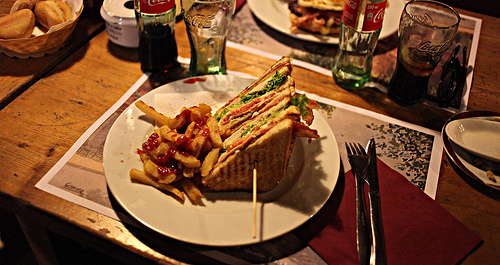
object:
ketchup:
[137, 110, 215, 177]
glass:
[179, 0, 237, 76]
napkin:
[298, 152, 486, 262]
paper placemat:
[382, 112, 447, 184]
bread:
[202, 119, 294, 192]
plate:
[102, 74, 342, 247]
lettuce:
[238, 71, 294, 106]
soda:
[332, 25, 375, 87]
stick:
[243, 167, 261, 239]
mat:
[36, 50, 443, 265]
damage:
[22, 100, 93, 143]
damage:
[474, 65, 491, 97]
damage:
[83, 214, 113, 235]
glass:
[398, 9, 450, 74]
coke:
[388, 61, 432, 102]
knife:
[367, 137, 388, 265]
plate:
[443, 118, 499, 163]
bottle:
[135, 1, 178, 74]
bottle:
[332, 2, 386, 90]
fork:
[342, 140, 372, 262]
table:
[2, 1, 499, 263]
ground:
[301, 67, 366, 109]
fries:
[129, 100, 220, 202]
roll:
[34, 0, 84, 32]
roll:
[0, 8, 34, 41]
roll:
[5, 0, 36, 15]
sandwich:
[198, 54, 321, 194]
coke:
[135, 23, 178, 76]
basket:
[4, 0, 85, 59]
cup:
[386, 0, 461, 111]